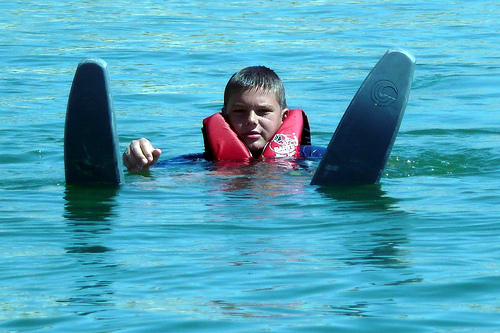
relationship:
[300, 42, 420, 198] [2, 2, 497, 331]
flipper in water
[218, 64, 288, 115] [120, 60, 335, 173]
hair belonging to person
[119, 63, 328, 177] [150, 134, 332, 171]
boy wearing shirt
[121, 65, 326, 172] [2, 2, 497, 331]
boy lying in water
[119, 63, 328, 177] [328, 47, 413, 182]
boy wearing ski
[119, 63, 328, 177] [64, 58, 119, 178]
boy wearing ski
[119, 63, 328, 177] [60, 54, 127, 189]
boy wearing boards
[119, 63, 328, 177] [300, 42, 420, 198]
boy wearing flipper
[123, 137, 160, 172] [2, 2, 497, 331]
hand floating above water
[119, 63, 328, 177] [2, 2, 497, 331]
boy floating in water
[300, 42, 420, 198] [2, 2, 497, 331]
flipper reflecting in water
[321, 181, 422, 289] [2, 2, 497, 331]
reflection casted in water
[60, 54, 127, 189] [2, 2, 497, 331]
boards reflecting in water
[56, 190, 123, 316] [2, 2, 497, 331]
reflection casted in water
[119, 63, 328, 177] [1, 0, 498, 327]
boy in ocean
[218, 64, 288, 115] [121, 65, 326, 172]
hair on boy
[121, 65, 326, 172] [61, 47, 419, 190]
boy wearing skis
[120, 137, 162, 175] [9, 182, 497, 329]
hand in water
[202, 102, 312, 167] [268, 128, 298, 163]
vest has design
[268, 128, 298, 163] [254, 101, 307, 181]
design on side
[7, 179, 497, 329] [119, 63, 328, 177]
waters where boy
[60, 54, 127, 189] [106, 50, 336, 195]
boards on boy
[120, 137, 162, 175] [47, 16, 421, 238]
hand of boy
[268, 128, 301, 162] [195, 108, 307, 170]
design on life guard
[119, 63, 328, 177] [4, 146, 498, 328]
boy in water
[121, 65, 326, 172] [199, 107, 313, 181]
boy wearing life guard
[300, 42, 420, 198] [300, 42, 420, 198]
flipper on flipper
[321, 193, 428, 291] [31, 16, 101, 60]
reflection suggest sunny day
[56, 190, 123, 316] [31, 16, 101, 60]
reflection suggest sunny day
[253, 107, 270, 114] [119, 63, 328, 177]
eye on boy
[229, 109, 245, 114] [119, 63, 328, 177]
eye on boy